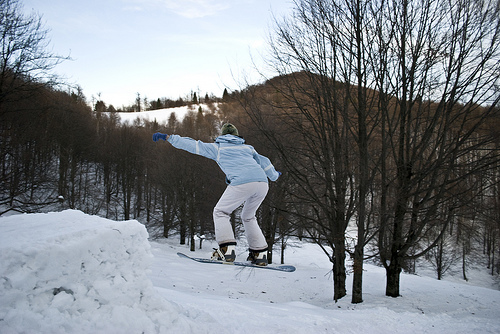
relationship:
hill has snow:
[79, 69, 322, 137] [94, 101, 224, 124]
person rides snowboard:
[149, 108, 283, 265] [172, 251, 298, 274]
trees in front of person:
[225, 1, 499, 303] [153, 124, 285, 265]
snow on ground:
[1, 207, 499, 332] [0, 207, 499, 332]